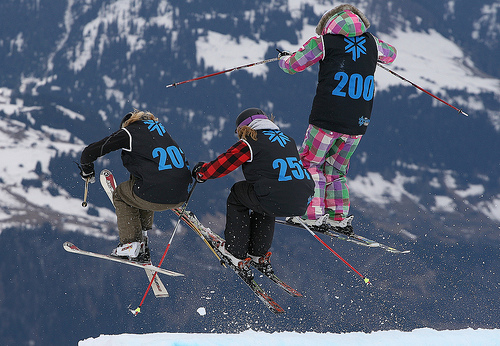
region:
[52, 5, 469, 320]
three skiers coming off if a ski jump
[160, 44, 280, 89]
red and silver ski pole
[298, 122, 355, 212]
plaid pants of a skiier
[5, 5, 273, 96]
mountain in the background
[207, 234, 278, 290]
ski boots and ski bindings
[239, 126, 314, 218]
black and blue vest skier is wearing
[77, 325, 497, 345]
snow that the skiers are skiing on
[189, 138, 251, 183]
left arm of skier in red plaid shirt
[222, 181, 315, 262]
crouched legs of skier coming off a ski jump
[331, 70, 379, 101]
the number '200' on the back of skiers top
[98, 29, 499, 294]
people that are skiing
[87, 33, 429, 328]
people jumping int he air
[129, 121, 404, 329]
skiers jumping in the air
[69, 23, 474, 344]
three people jumping in the air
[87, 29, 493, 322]
three skiers in the air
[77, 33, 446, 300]
three people wearing skies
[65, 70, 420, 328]
people that are wearing skies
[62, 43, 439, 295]
people holding ski poles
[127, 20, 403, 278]
three people holding ski poles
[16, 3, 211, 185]
snow covering the ground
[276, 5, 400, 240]
skier is number 200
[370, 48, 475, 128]
snow pole on right hand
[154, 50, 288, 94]
snow pole on left hand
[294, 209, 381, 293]
snow pole on right hand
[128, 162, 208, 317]
snow pole on left hand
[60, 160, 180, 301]
skis color white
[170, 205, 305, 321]
skis color red and black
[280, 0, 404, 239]
man wears a squared winter clothes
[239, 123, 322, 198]
a black vest with blue letters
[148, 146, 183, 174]
number twenty on jacket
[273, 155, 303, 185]
number twenty five on jacket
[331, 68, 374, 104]
number two hundred on jacket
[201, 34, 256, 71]
snow on big mountains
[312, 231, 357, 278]
red part of ski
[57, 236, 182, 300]
white ski's under feet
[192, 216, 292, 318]
black and brown skis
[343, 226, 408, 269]
back of grey skis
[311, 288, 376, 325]
snow in mid air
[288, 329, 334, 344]
white snow on ground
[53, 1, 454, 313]
three skiiers in the air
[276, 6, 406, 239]
pink and green checked ski outfit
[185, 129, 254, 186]
red and black sleeve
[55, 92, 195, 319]
crouched skiier during jump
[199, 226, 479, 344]
snow spray beneath skis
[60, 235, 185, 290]
white ski boot and ski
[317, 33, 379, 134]
black vest with blue number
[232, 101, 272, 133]
black hat with purple rim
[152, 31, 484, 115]
two red ski poles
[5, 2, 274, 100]
pine trees on mountain side